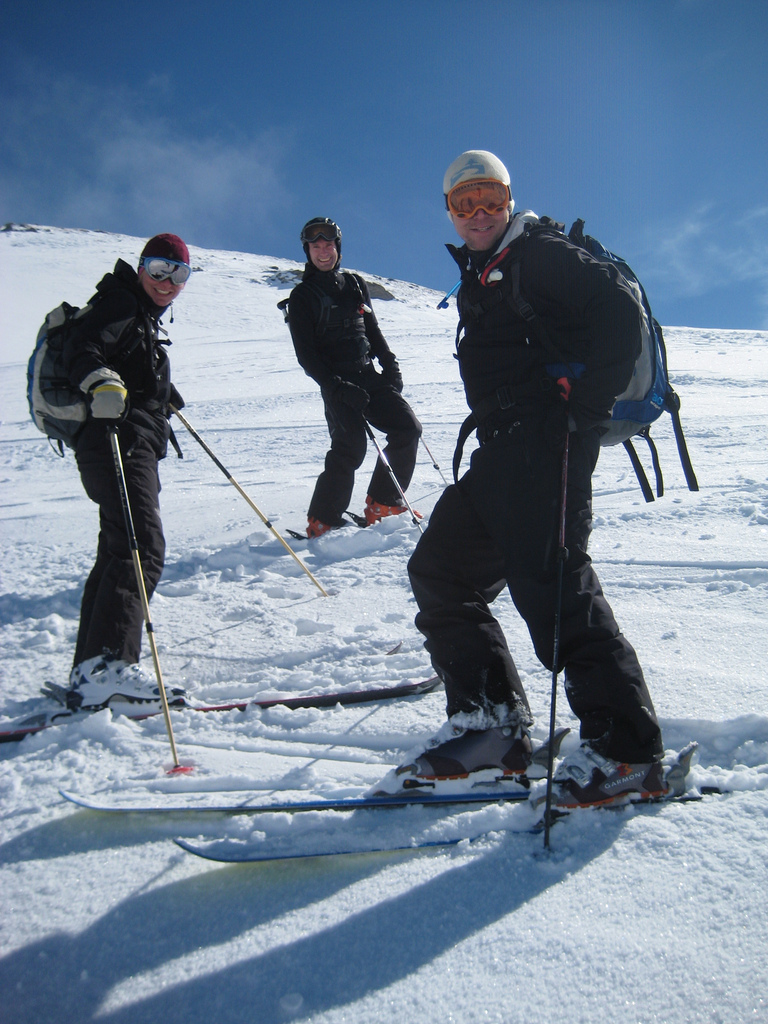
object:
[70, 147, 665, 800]
person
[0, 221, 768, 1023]
ground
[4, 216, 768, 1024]
slope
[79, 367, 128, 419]
glove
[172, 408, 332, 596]
ski pole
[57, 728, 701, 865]
skis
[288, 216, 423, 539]
skier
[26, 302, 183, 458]
backpack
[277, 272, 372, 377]
backpack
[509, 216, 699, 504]
backpack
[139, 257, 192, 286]
black goggles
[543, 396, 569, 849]
pole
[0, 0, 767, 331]
sky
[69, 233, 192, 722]
man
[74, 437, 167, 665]
pants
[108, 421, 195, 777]
poles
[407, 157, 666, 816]
man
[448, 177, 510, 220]
goggles